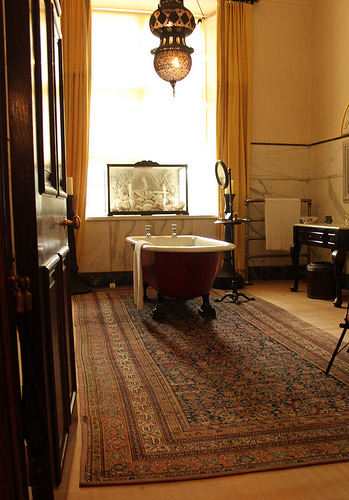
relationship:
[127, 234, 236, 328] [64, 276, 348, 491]
bathtub in middle of floor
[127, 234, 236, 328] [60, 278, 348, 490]
bathtub sitting on rug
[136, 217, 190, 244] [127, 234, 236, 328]
two knobs are on bathtub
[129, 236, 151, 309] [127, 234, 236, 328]
towel hanging from bathtub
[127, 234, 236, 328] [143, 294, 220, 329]
bathtub has feet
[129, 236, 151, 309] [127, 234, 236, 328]
towel hangs from bathtub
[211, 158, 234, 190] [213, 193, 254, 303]
mirror on stand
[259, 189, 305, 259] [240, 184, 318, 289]
towel hanging from rack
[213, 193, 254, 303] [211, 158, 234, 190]
stand has mirror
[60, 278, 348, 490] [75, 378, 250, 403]
rug has patterns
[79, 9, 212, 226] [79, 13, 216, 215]
window has window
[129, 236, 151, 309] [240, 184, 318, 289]
towel hanging on rack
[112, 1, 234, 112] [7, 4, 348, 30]
chandelier hangs from ceiling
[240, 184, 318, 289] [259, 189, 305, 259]
rack holds towel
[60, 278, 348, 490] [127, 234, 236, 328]
rug under bathtub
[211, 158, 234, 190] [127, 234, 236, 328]
mirror next to bathtub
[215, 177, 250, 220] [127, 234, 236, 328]
candle stick next to bathtub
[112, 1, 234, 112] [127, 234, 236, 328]
chandelier above bathtub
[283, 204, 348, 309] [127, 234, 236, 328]
table by bathtub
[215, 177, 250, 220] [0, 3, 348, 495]
candle stick in bathroom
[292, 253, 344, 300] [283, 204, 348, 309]
garbage can under table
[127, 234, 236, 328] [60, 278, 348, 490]
bathtub on rug